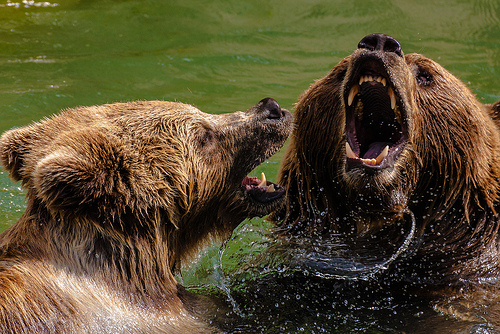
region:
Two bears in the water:
[11, 33, 498, 330]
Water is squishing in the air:
[268, 183, 405, 299]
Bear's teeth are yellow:
[326, 63, 410, 187]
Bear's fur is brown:
[21, 91, 213, 332]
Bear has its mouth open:
[302, 56, 434, 186]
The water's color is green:
[16, 11, 306, 92]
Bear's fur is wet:
[20, 91, 226, 333]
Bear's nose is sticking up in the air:
[313, 26, 435, 123]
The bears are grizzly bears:
[16, 15, 463, 331]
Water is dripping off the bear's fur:
[184, 221, 265, 323]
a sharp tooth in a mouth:
[344, 81, 361, 113]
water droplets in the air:
[220, 249, 259, 271]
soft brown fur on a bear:
[94, 143, 166, 195]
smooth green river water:
[144, 20, 246, 71]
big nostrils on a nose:
[361, 28, 401, 56]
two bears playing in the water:
[49, 31, 459, 283]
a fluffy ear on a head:
[34, 129, 109, 200]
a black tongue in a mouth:
[358, 139, 390, 149]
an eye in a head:
[408, 51, 440, 93]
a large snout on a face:
[231, 97, 286, 219]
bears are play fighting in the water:
[26, 70, 495, 284]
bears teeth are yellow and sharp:
[310, 72, 413, 175]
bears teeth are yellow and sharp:
[236, 149, 302, 206]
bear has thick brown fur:
[2, 92, 289, 327]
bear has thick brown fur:
[280, 61, 498, 311]